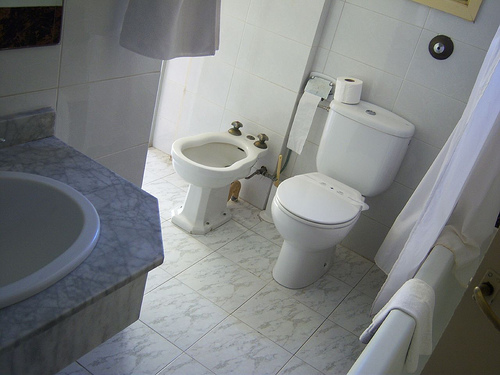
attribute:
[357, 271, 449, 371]
towel — small, white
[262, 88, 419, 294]
toilet — white, down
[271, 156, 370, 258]
lid — white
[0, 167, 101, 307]
sink — white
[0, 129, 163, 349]
counter — gray, marble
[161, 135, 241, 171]
toilet —  white 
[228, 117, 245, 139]
knob — brass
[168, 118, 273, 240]
toilet — white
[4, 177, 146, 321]
sink — white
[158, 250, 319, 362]
floor — white, tiled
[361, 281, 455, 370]
towel — white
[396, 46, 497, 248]
curtain — white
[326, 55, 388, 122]
toilet tissue — white, rolled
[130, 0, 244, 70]
towel — white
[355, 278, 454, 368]
mat — white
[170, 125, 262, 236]
bidet — white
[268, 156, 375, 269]
lid — closed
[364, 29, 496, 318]
shower curtain — white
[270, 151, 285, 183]
handle — yellow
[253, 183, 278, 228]
container — white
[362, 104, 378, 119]
button — silver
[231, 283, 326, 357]
tile — white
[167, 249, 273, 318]
tile — white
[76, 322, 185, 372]
tile — white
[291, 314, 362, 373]
tile — white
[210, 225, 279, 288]
tile — white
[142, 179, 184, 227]
tile — white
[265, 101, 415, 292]
toilet — bathroom, white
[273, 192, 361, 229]
seat — down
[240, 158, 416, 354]
toilet — white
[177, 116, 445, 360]
toilet — white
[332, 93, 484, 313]
curtain — white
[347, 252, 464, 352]
towel — white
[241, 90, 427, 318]
toilet — white 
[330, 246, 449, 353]
towel — white 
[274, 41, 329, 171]
pipe — silver 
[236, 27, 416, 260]
pipe — silver 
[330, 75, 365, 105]
paper —  toilet, white , roll  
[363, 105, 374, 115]
button — chrome 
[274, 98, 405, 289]
toilet — white